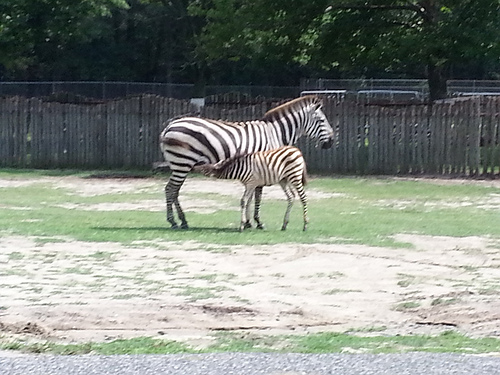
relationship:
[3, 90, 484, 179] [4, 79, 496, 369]
fence in park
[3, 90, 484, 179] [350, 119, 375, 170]
fence has whole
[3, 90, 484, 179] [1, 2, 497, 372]
fence in park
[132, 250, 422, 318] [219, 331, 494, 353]
dirt patch in grass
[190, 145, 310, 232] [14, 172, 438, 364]
baby zebra in grass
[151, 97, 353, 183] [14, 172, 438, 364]
zebra in grass